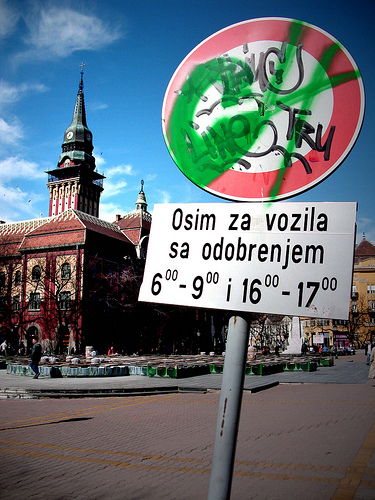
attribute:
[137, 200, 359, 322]
sign — white, black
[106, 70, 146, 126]
sky — blue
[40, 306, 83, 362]
window — small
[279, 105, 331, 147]
paint — black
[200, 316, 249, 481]
cow — metal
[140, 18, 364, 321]
sign — double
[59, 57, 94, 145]
steeple — green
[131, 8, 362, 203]
sign — red, white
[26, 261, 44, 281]
window — small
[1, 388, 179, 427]
lines — yellow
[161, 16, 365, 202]
sign — red, red and white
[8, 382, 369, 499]
roadway — brick, yellow striped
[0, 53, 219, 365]
building — red 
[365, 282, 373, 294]
window — small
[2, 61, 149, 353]
building — red and cream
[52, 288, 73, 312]
window — small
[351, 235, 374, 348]
building — tan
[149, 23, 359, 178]
spay paint — green, spray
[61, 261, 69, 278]
window — small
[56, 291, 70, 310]
window — small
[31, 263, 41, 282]
window — small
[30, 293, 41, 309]
window — small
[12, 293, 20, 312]
window — small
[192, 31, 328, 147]
sign — circular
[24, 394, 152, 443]
line — yellow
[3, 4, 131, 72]
cloud — thin, white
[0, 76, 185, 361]
church — red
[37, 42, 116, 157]
steeple — green